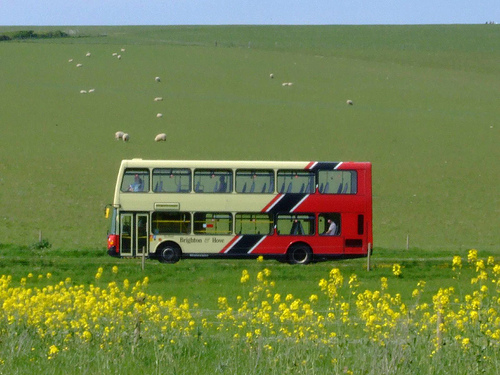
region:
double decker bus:
[92, 149, 379, 264]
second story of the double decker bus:
[89, 149, 380, 214]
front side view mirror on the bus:
[94, 198, 126, 224]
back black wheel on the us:
[279, 230, 313, 275]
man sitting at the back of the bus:
[298, 204, 349, 244]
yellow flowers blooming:
[63, 256, 423, 355]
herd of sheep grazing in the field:
[46, 42, 241, 157]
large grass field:
[343, 53, 462, 122]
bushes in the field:
[0, 25, 81, 56]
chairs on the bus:
[166, 170, 346, 192]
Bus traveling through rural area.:
[30, 35, 458, 346]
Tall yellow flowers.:
[6, 255, 481, 362]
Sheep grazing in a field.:
[36, 31, 361, 151]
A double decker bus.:
[94, 144, 386, 273]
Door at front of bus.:
[113, 204, 159, 261]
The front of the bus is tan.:
[104, 147, 396, 272]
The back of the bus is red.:
[213, 150, 385, 274]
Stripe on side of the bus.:
[213, 152, 343, 267]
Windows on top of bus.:
[106, 153, 362, 198]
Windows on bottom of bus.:
[146, 191, 350, 247]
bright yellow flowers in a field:
[0, 256, 498, 373]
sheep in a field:
[57, 46, 379, 148]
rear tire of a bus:
[283, 237, 313, 267]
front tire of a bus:
[154, 240, 185, 266]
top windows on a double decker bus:
[119, 167, 362, 193]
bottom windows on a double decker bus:
[152, 210, 343, 236]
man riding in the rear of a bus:
[319, 215, 339, 237]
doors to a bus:
[118, 211, 148, 254]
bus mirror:
[101, 202, 111, 217]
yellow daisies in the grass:
[0, 250, 499, 370]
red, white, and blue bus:
[108, 147, 375, 264]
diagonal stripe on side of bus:
[227, 147, 342, 261]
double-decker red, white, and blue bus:
[103, 157, 373, 264]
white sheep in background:
[56, 43, 369, 151]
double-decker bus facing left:
[101, 157, 377, 262]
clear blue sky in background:
[0, 2, 498, 26]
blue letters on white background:
[174, 233, 229, 246]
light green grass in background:
[4, 25, 499, 251]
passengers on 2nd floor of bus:
[113, 154, 368, 209]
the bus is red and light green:
[61, 117, 397, 365]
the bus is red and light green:
[135, 123, 350, 290]